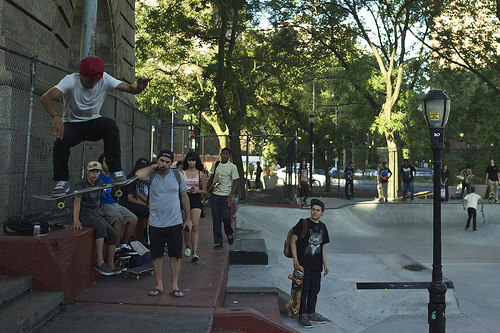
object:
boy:
[32, 55, 154, 210]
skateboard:
[32, 174, 142, 209]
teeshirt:
[292, 217, 330, 272]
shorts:
[148, 222, 183, 258]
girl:
[179, 151, 209, 262]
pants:
[52, 116, 124, 181]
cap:
[78, 56, 106, 80]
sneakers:
[49, 180, 71, 198]